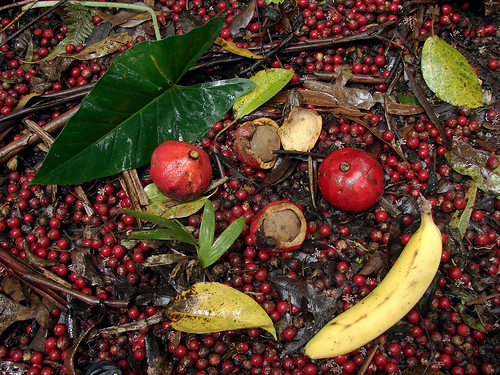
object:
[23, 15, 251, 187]
leaf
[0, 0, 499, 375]
ground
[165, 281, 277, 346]
leaf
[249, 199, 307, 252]
nut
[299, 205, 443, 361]
banana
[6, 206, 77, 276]
berries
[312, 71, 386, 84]
twigs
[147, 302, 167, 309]
stem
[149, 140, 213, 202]
pomegranate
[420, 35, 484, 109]
leaves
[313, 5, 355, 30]
cranberries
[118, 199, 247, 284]
plant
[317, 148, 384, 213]
pomegranates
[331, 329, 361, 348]
peel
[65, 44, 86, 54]
cranberry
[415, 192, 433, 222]
stem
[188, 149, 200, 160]
stem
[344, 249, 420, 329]
marks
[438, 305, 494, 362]
coffee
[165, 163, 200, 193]
skin